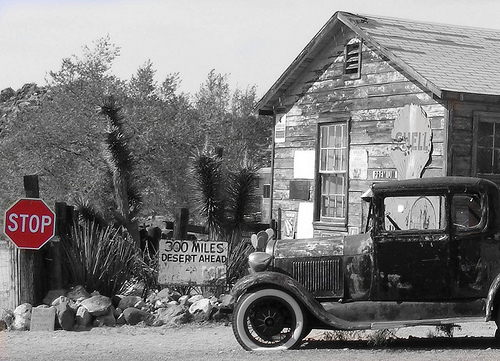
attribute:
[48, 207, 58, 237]
border — white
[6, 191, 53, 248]
sign — red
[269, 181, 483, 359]
car — abandoned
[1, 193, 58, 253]
stop sign — red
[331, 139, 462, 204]
sign —  Premium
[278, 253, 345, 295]
grate — small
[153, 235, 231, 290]
sign — white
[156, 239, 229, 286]
sign —  White and black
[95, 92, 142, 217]
needles — pine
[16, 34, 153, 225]
tree — tall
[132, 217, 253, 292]
sign —  White and black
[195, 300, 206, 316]
stones —  gray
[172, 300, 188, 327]
stones —  gray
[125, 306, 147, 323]
stones —  gray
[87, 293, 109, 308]
stones —  gray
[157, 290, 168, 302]
stones —  gray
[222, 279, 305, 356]
tire —  Flat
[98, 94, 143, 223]
cactus tree —  tall,   cactus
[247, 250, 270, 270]
headlight — at side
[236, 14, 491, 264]
house — old,  timber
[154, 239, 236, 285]
sign —  White and black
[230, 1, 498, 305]
building — behind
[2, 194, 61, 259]
sign — red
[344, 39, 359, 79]
attic vent —  of Attic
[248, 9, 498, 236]
old building —  old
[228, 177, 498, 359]
car —  black,  old,  worn antique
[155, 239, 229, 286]
desert sign —  for Desert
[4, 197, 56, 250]
sign —  Posted ,  red,  stop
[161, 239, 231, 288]
sign —  White and black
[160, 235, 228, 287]
sign —  White and black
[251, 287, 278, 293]
wall —  white